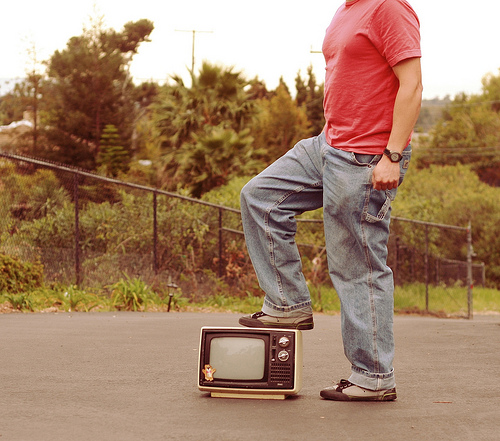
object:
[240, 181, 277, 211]
knee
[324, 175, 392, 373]
leg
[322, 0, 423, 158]
shirt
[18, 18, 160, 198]
pine trees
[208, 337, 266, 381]
screen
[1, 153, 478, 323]
fence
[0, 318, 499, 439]
ground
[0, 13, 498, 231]
trees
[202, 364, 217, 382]
bear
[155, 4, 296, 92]
cloudy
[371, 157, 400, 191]
hand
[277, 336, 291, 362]
knobs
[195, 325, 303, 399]
television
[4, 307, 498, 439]
concrete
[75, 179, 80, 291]
poles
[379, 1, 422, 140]
arm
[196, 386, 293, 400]
white case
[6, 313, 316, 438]
road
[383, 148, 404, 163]
watch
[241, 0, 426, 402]
man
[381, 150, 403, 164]
wrist